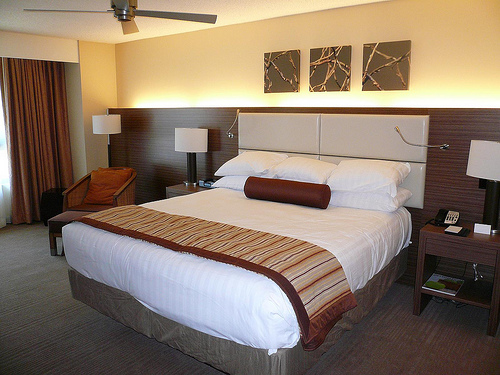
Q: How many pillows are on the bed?
A: Seven.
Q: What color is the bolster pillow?
A: Brown.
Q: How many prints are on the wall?
A: Three.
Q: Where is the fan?
A: On the ceiling.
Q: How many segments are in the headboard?
A: Four.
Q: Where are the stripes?
A: On a blanket.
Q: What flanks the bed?
A: Two nightstands.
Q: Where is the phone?
A: To the right of the bed.